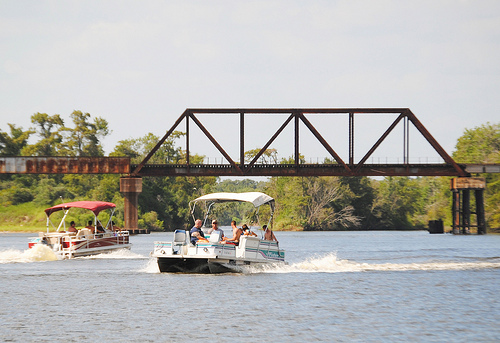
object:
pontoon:
[28, 201, 130, 257]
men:
[191, 218, 207, 245]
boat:
[152, 191, 285, 275]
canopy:
[189, 191, 274, 242]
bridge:
[3, 107, 500, 235]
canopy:
[44, 200, 115, 230]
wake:
[1, 243, 58, 265]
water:
[0, 274, 500, 342]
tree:
[304, 182, 363, 229]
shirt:
[190, 227, 204, 245]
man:
[222, 219, 242, 244]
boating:
[29, 198, 131, 257]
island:
[262, 148, 497, 230]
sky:
[2, 1, 494, 100]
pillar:
[120, 178, 148, 233]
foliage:
[457, 118, 500, 163]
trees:
[0, 110, 113, 156]